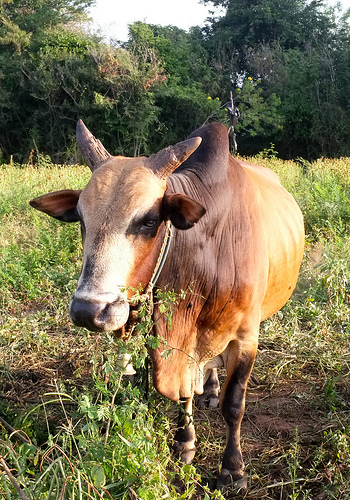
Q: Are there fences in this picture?
A: No, there are no fences.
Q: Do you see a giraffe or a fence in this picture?
A: No, there are no fences or giraffes.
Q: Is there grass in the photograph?
A: Yes, there is grass.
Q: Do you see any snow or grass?
A: Yes, there is grass.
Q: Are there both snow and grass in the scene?
A: No, there is grass but no snow.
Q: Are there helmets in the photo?
A: No, there are no helmets.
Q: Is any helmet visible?
A: No, there are no helmets.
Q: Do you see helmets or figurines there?
A: No, there are no helmets or figurines.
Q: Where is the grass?
A: The grass is on the ground.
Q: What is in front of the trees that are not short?
A: The grass is in front of the trees.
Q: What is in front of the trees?
A: The grass is in front of the trees.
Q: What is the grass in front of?
A: The grass is in front of the trees.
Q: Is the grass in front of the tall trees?
A: Yes, the grass is in front of the trees.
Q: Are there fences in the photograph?
A: No, there are no fences.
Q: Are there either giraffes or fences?
A: No, there are no fences or giraffes.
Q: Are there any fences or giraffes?
A: No, there are no fences or giraffes.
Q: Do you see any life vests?
A: No, there are no life vests.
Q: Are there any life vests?
A: No, there are no life vests.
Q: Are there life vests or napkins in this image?
A: No, there are no life vests or napkins.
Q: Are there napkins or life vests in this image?
A: No, there are no life vests or napkins.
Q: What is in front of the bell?
A: The bushes are in front of the bell.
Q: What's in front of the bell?
A: The bushes are in front of the bell.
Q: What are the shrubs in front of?
A: The shrubs are in front of the bell.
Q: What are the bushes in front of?
A: The shrubs are in front of the bell.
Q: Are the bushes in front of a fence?
A: No, the bushes are in front of a bell.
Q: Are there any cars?
A: No, there are no cars.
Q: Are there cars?
A: No, there are no cars.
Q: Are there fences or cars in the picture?
A: No, there are no cars or fences.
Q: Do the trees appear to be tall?
A: Yes, the trees are tall.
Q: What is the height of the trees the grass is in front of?
A: The trees are tall.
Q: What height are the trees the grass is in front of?
A: The trees are tall.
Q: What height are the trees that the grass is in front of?
A: The trees are tall.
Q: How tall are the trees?
A: The trees are tall.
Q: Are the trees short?
A: No, the trees are tall.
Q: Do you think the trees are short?
A: No, the trees are tall.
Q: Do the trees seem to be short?
A: No, the trees are tall.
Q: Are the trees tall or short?
A: The trees are tall.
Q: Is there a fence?
A: No, there are no fences.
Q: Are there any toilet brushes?
A: No, there are no toilet brushes.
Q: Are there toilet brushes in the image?
A: No, there are no toilet brushes.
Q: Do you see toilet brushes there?
A: No, there are no toilet brushes.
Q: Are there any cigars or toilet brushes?
A: No, there are no toilet brushes or cigars.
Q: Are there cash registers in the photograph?
A: No, there are no cash registers.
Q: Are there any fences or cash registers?
A: No, there are no cash registers or fences.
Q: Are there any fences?
A: No, there are no fences.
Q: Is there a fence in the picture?
A: No, there are no fences.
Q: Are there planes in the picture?
A: No, there are no planes.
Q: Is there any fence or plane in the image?
A: No, there are no airplanes or fences.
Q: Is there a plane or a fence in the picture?
A: No, there are no airplanes or fences.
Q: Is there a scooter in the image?
A: No, there are no scooters.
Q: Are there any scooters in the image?
A: No, there are no scooters.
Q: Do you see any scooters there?
A: No, there are no scooters.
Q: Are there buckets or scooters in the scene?
A: No, there are no scooters or buckets.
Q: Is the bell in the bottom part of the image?
A: Yes, the bell is in the bottom of the image.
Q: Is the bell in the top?
A: No, the bell is in the bottom of the image.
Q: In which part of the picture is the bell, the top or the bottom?
A: The bell is in the bottom of the image.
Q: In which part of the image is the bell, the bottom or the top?
A: The bell is in the bottom of the image.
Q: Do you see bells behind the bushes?
A: Yes, there is a bell behind the bushes.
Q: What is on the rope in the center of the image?
A: The bell is on the rope.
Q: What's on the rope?
A: The bell is on the rope.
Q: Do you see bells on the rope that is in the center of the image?
A: Yes, there is a bell on the rope.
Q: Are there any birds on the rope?
A: No, there is a bell on the rope.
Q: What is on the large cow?
A: The bell is on the cow.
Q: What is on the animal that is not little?
A: The bell is on the cow.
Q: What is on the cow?
A: The bell is on the cow.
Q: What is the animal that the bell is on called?
A: The animal is a cow.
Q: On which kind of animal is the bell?
A: The bell is on the cow.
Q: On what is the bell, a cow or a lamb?
A: The bell is on a cow.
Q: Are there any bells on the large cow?
A: Yes, there is a bell on the cow.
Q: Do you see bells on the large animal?
A: Yes, there is a bell on the cow.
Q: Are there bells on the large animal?
A: Yes, there is a bell on the cow.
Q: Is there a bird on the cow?
A: No, there is a bell on the cow.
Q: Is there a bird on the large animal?
A: No, there is a bell on the cow.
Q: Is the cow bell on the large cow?
A: Yes, the bell is on the cow.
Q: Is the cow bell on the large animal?
A: Yes, the bell is on the cow.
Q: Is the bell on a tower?
A: No, the bell is on the cow.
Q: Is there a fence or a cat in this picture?
A: No, there are no fences or cats.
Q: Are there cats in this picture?
A: No, there are no cats.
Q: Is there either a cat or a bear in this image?
A: No, there are no cats or bears.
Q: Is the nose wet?
A: Yes, the nose is wet.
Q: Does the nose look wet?
A: Yes, the nose is wet.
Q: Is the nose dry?
A: No, the nose is wet.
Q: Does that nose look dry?
A: No, the nose is wet.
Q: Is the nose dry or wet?
A: The nose is wet.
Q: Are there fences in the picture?
A: No, there are no fences.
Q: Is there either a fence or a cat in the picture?
A: No, there are no fences or cats.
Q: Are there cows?
A: Yes, there is a cow.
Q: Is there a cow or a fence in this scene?
A: Yes, there is a cow.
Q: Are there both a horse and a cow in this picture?
A: No, there is a cow but no horses.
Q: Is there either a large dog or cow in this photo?
A: Yes, there is a large cow.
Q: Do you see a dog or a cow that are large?
A: Yes, the cow is large.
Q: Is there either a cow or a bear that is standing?
A: Yes, the cow is standing.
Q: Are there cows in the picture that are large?
A: Yes, there is a large cow.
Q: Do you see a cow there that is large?
A: Yes, there is a cow that is large.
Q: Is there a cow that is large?
A: Yes, there is a cow that is large.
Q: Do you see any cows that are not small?
A: Yes, there is a large cow.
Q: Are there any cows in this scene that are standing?
A: Yes, there is a cow that is standing.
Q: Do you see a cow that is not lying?
A: Yes, there is a cow that is standing .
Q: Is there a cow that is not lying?
A: Yes, there is a cow that is standing.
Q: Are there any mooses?
A: No, there are no mooses.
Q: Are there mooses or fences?
A: No, there are no mooses or fences.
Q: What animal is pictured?
A: The animal is a cow.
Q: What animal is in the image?
A: The animal is a cow.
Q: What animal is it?
A: The animal is a cow.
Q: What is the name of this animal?
A: This is a cow.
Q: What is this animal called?
A: This is a cow.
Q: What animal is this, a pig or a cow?
A: This is a cow.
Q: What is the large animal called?
A: The animal is a cow.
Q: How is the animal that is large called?
A: The animal is a cow.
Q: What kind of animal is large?
A: The animal is a cow.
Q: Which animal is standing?
A: The animal is a cow.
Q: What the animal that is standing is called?
A: The animal is a cow.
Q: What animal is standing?
A: The animal is a cow.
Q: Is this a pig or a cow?
A: This is a cow.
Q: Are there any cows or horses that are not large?
A: No, there is a cow but it is large.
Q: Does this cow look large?
A: Yes, the cow is large.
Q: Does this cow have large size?
A: Yes, the cow is large.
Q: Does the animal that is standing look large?
A: Yes, the cow is large.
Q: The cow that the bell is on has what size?
A: The cow is large.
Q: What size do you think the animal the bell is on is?
A: The cow is large.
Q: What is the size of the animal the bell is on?
A: The cow is large.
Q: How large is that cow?
A: The cow is large.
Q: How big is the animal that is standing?
A: The cow is large.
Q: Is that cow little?
A: No, the cow is large.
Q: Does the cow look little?
A: No, the cow is large.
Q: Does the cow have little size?
A: No, the cow is large.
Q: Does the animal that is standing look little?
A: No, the cow is large.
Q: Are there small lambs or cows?
A: No, there is a cow but it is large.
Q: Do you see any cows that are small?
A: No, there is a cow but it is large.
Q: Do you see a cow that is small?
A: No, there is a cow but it is large.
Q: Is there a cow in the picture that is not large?
A: No, there is a cow but it is large.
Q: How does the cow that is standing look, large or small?
A: The cow is large.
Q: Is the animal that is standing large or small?
A: The cow is large.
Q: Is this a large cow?
A: Yes, this is a large cow.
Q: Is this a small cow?
A: No, this is a large cow.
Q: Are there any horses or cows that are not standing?
A: No, there is a cow but it is standing.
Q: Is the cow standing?
A: Yes, the cow is standing.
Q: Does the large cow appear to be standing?
A: Yes, the cow is standing.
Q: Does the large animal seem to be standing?
A: Yes, the cow is standing.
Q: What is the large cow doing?
A: The cow is standing.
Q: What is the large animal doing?
A: The cow is standing.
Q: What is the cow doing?
A: The cow is standing.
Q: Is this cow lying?
A: No, the cow is standing.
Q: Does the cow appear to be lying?
A: No, the cow is standing.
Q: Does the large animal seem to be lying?
A: No, the cow is standing.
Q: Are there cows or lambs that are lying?
A: No, there is a cow but it is standing.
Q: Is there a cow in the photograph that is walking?
A: No, there is a cow but it is standing.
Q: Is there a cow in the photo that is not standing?
A: No, there is a cow but it is standing.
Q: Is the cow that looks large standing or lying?
A: The cow is standing.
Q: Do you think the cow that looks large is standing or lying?
A: The cow is standing.